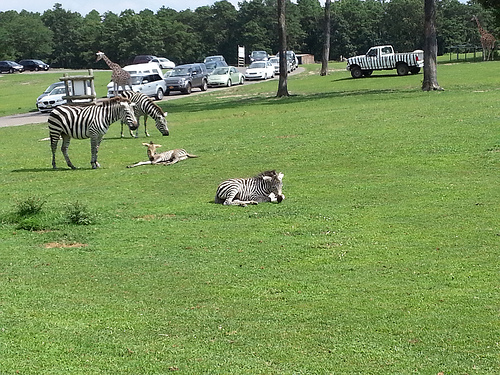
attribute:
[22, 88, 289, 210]
zebras — young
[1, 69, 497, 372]
field — here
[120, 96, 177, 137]
zebra — graving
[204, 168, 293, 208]
zebra — baby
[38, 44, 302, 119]
cars — lined up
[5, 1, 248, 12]
sky — blue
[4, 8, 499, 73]
trees — green, here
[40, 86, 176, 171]
two zebras — standing